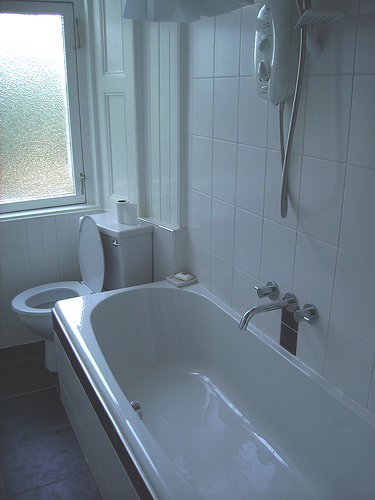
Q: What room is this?
A: Bathroom.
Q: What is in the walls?
A: Tiles.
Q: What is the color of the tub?
A: White.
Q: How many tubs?
A: 1.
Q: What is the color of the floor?
A: Grey.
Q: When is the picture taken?
A: Daytime.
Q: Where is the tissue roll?
A: Top of the flush.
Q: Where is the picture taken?
A: In a bathroom.